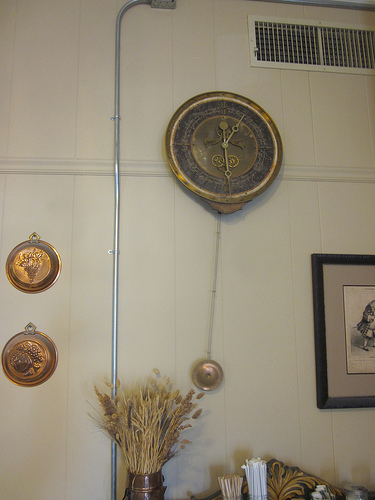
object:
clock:
[164, 88, 284, 216]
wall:
[3, 2, 370, 499]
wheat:
[83, 366, 204, 477]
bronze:
[0, 322, 59, 388]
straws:
[241, 457, 270, 500]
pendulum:
[189, 210, 223, 392]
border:
[311, 252, 375, 409]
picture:
[322, 264, 375, 400]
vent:
[246, 13, 375, 76]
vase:
[121, 464, 168, 500]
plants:
[190, 408, 204, 422]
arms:
[221, 114, 244, 149]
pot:
[4, 231, 61, 296]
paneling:
[118, 173, 177, 382]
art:
[310, 250, 375, 410]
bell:
[189, 357, 224, 392]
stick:
[207, 211, 222, 360]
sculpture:
[189, 457, 348, 499]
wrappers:
[240, 453, 268, 499]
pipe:
[109, 0, 152, 500]